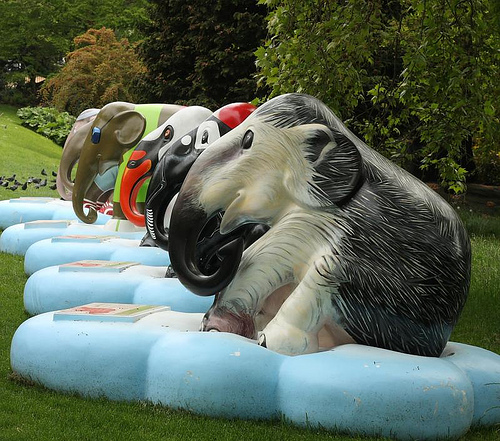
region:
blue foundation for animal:
[44, 291, 244, 428]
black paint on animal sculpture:
[325, 167, 477, 325]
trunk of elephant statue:
[128, 209, 262, 286]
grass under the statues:
[25, 390, 150, 437]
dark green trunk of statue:
[54, 123, 124, 265]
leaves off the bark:
[370, 95, 495, 156]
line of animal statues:
[52, 109, 363, 274]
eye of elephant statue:
[225, 123, 272, 155]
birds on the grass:
[2, 164, 49, 198]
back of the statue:
[403, 173, 493, 298]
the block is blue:
[46, 311, 468, 426]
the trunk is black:
[158, 201, 243, 296]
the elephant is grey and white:
[223, 128, 457, 347]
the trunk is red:
[112, 144, 177, 249]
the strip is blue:
[83, 95, 169, 150]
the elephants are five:
[59, 106, 457, 365]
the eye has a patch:
[82, 115, 117, 185]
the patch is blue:
[86, 118, 111, 165]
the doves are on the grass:
[13, 163, 60, 203]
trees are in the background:
[133, 68, 473, 90]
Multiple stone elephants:
[37, 77, 478, 370]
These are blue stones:
[2, 180, 497, 438]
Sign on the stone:
[44, 282, 176, 337]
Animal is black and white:
[194, 105, 484, 365]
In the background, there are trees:
[258, 7, 496, 190]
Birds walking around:
[5, 148, 65, 194]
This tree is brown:
[35, 17, 156, 114]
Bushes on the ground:
[7, 95, 74, 155]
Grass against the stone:
[12, 362, 403, 437]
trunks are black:
[160, 186, 264, 300]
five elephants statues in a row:
[12, 85, 472, 422]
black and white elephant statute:
[169, 103, 450, 340]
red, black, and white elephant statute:
[138, 110, 261, 240]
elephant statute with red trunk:
[124, 102, 198, 239]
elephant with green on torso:
[79, 98, 184, 229]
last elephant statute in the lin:
[57, 107, 113, 202]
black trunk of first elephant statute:
[160, 196, 267, 302]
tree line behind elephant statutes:
[22, 40, 497, 202]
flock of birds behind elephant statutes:
[1, 161, 57, 199]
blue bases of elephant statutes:
[2, 198, 499, 422]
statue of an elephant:
[0, 88, 499, 440]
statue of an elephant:
[18, 98, 263, 318]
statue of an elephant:
[0, 100, 187, 254]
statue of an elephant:
[0, 105, 103, 232]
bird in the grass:
[18, 179, 30, 193]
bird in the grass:
[38, 164, 48, 178]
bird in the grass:
[38, 175, 50, 187]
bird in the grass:
[2, 170, 18, 183]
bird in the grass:
[11, 176, 26, 186]